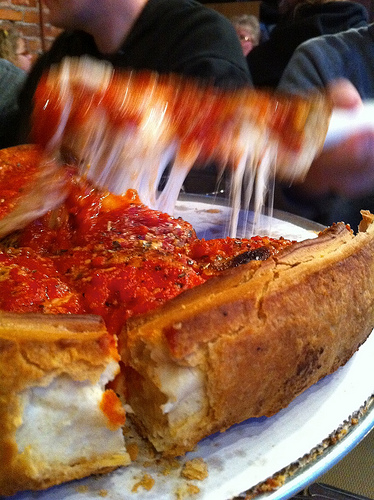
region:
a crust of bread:
[178, 445, 205, 483]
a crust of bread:
[58, 328, 111, 371]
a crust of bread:
[126, 462, 163, 491]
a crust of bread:
[161, 399, 223, 444]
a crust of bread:
[213, 355, 241, 379]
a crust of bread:
[249, 356, 286, 403]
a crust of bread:
[77, 399, 119, 443]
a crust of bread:
[25, 312, 67, 369]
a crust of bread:
[165, 311, 219, 368]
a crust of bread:
[294, 296, 324, 348]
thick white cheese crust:
[3, 322, 130, 480]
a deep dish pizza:
[2, 143, 372, 495]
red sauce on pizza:
[0, 145, 279, 323]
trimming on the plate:
[223, 390, 372, 498]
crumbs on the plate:
[75, 452, 209, 498]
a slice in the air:
[29, 60, 335, 171]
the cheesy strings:
[72, 129, 283, 239]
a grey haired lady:
[230, 10, 262, 56]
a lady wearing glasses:
[1, 15, 33, 69]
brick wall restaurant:
[0, 1, 64, 58]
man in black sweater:
[1, 0, 252, 110]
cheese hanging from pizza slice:
[51, 60, 337, 190]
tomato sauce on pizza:
[4, 174, 186, 310]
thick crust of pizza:
[134, 220, 370, 456]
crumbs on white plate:
[121, 448, 205, 498]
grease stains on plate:
[210, 426, 260, 476]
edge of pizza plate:
[244, 377, 372, 498]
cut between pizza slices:
[86, 310, 172, 467]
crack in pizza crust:
[194, 256, 285, 355]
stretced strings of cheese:
[95, 135, 277, 235]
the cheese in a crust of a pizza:
[2, 313, 129, 491]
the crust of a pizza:
[266, 267, 372, 411]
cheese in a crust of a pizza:
[128, 334, 214, 457]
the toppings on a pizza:
[94, 219, 177, 294]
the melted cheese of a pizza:
[81, 121, 284, 184]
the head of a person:
[230, 12, 263, 61]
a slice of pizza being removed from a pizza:
[35, 47, 338, 165]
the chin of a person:
[42, 8, 82, 30]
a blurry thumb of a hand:
[324, 75, 360, 114]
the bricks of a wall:
[20, 5, 43, 37]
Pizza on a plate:
[0, 110, 348, 447]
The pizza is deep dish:
[56, 15, 235, 464]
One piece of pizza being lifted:
[35, 45, 339, 252]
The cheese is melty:
[31, 106, 281, 218]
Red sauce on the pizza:
[0, 151, 255, 305]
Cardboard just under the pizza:
[7, 362, 360, 475]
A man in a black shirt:
[23, 6, 285, 190]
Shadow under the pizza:
[212, 204, 255, 241]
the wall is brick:
[0, 0, 88, 63]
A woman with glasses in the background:
[0, 24, 41, 77]